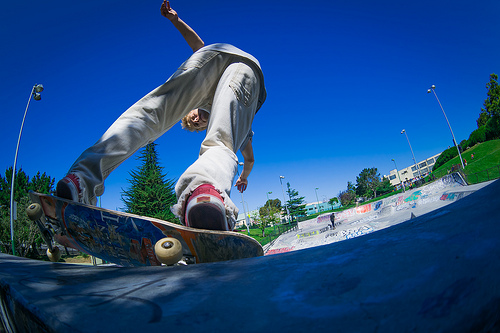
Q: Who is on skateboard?
A: A boy.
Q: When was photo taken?
A: During day.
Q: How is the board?
A: Side of ramp.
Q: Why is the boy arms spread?
A: To keep balance.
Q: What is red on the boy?
A: Shoes.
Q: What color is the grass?
A: Green.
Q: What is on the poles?
A: Lights.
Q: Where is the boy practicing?
A: Skate park.